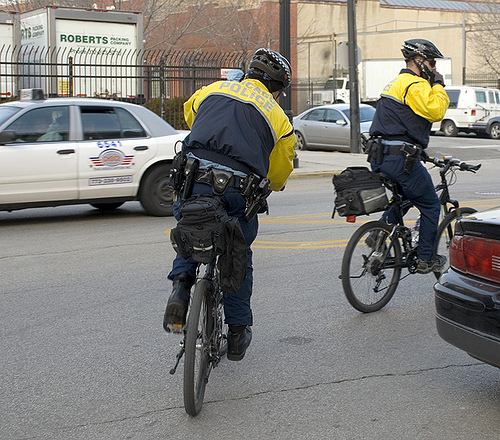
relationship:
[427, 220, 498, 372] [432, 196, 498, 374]
back of car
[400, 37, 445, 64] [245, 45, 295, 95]
helmet on man's head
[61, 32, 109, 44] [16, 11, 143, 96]
roberts on truck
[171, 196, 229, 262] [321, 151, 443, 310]
bag on bike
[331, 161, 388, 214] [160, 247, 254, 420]
bag on bike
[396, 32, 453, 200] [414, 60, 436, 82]
he talks on phone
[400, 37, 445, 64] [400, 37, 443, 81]
helmet on head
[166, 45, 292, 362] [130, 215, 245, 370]
he riding bike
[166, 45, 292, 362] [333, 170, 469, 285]
he on bike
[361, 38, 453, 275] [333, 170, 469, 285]
he on bike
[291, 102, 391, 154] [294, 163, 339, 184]
car by curb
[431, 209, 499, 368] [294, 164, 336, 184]
back by curb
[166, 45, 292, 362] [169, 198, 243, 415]
he riding bike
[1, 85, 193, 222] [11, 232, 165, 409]
car in road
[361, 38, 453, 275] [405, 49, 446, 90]
he holding phone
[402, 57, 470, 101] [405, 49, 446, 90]
hand holding phone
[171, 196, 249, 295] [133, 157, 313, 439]
bag on bike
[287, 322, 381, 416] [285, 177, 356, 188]
road has edge